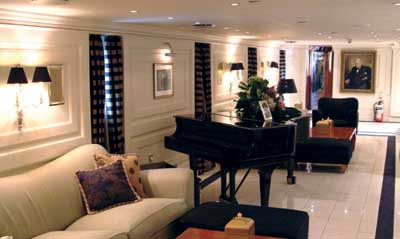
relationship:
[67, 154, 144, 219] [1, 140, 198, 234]
pillow on sofa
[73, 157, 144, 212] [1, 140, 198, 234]
pillow on sofa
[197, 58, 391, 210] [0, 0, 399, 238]
piano in house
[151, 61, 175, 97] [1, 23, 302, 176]
picture in wall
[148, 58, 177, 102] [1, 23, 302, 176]
picture in wall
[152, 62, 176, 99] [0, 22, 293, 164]
frame on wall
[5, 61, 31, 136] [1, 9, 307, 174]
light on wall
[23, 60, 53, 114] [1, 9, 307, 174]
light on wall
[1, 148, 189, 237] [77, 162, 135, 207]
couch has pillow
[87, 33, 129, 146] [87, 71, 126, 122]
curtain on wall